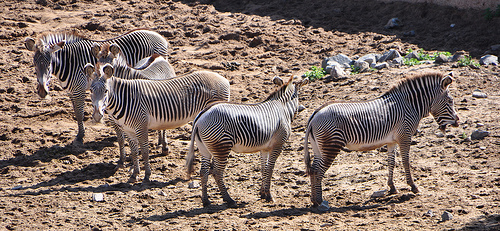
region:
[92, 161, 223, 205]
shadow cast on the sand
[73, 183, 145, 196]
white paper on the ground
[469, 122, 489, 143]
large stone on the ground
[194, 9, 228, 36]
large mound of dirt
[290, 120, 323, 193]
long tail on zebra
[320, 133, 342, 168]
black spot on zebra's hind leg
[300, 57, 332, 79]
small patch of green bush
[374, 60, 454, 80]
mane of comb on zebra's back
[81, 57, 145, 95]
large ears on zebra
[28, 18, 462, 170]
cluster of black and white zebraz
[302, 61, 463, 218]
a zebra standing on the ground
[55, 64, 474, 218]
many zebra standing together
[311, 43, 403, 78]
a row of rocks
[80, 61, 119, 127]
a zebra's head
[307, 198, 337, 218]
a zebra's back hoof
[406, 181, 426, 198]
a zebra's front hoof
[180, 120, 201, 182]
a zebra's tail hanging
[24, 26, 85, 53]
a zebra's mane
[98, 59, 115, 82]
a zebra's left ear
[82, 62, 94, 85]
a zebra's right ear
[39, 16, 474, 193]
Picture taken outside.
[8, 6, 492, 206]
Picture taken during the day time.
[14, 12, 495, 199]
The sun is shinning.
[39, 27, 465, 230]
Zebras standing on the ground.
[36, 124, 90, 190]
The ground is dirt.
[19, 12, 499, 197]
The zebras have white and black stripes.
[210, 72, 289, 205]
One zebra is small than the rest.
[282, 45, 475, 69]
Rocks on the ground.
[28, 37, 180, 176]
Three zebras facing the camera.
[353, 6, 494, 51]
Shadow of the wall.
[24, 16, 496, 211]
group of zebras standing on dirt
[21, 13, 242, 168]
three zebras facing left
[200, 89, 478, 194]
two zebras facing right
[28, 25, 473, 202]
black and white striped zebras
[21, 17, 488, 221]
dirt ground covered in rocks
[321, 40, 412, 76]
group of grey rocks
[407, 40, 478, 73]
patch of green grass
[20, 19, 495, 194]
group of wild animals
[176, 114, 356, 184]
two zebra tails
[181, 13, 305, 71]
dirt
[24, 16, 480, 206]
Five zebras in the field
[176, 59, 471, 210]
Two zebras facing right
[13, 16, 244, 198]
Three zebras facing left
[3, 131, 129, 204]
Shadows of zebras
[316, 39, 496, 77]
Small stones in zebra pen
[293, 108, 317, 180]
Tail of zebra is long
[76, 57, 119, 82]
Ears of zebra are round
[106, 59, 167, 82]
Mane of zebra is white and black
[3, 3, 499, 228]
Pen of zebra is cover with soil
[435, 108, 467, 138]
Muzzle of zebra is open